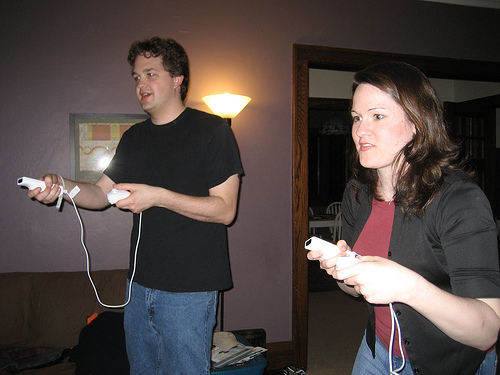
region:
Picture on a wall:
[65, 109, 166, 189]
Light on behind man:
[201, 85, 253, 121]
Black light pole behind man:
[219, 117, 231, 334]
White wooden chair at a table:
[328, 197, 350, 244]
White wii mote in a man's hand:
[12, 173, 67, 201]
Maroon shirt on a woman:
[360, 201, 407, 355]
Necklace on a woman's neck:
[375, 175, 402, 210]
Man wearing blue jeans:
[113, 280, 218, 373]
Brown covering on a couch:
[6, 272, 135, 369]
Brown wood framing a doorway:
[287, 40, 314, 367]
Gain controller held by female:
[297, 228, 395, 305]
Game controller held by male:
[2, 163, 76, 213]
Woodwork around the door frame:
[290, 40, 311, 212]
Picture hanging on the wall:
[65, 105, 157, 187]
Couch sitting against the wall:
[6, 254, 231, 374]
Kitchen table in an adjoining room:
[304, 193, 346, 232]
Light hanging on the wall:
[193, 78, 254, 128]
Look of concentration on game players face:
[334, 58, 419, 179]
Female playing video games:
[305, 63, 498, 360]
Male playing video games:
[82, 17, 244, 361]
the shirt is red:
[352, 202, 390, 269]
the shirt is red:
[336, 198, 430, 336]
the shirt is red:
[340, 212, 400, 280]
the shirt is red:
[376, 235, 413, 305]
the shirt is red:
[356, 195, 407, 257]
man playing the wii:
[17, 18, 252, 360]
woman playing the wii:
[284, 40, 477, 365]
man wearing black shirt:
[32, 19, 238, 364]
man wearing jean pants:
[24, 17, 236, 361]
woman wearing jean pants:
[302, 37, 485, 366]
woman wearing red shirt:
[302, 41, 480, 360]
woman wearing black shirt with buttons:
[297, 57, 482, 369]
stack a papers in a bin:
[205, 323, 263, 367]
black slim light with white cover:
[207, 88, 253, 338]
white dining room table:
[305, 188, 350, 266]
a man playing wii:
[21, 36, 245, 371]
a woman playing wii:
[303, 60, 495, 374]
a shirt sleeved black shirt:
[103, 108, 238, 290]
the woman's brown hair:
[353, 61, 475, 208]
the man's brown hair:
[130, 38, 188, 98]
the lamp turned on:
[202, 92, 249, 118]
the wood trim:
[291, 41, 311, 359]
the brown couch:
[3, 274, 74, 371]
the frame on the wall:
[69, 112, 151, 177]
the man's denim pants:
[123, 277, 214, 373]